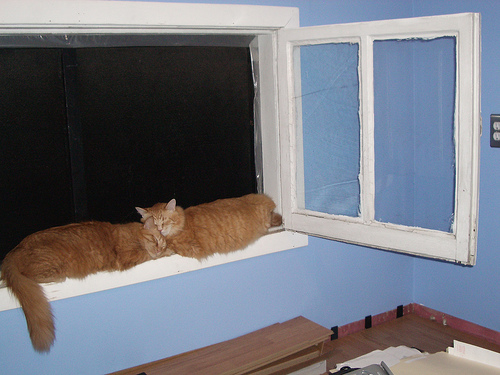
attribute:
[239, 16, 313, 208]
frame — white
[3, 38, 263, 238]
window — open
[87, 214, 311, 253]
cats — yellow, sleeping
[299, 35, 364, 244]
window — glass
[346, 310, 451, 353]
flooring — wood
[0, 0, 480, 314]
frame — white